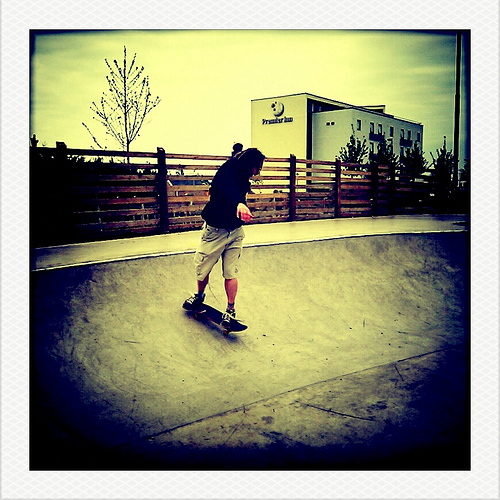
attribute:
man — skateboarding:
[175, 145, 271, 325]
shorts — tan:
[179, 224, 245, 285]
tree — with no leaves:
[74, 46, 165, 165]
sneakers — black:
[177, 292, 245, 330]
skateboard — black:
[202, 306, 223, 331]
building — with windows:
[250, 92, 422, 204]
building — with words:
[246, 90, 431, 187]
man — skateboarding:
[187, 134, 269, 321]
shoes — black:
[177, 293, 239, 330]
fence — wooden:
[31, 131, 470, 239]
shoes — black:
[178, 288, 240, 329]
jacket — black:
[198, 160, 249, 229]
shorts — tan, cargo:
[196, 222, 243, 279]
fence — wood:
[43, 118, 454, 233]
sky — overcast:
[205, 44, 386, 89]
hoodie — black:
[200, 158, 250, 232]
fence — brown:
[23, 144, 460, 246]